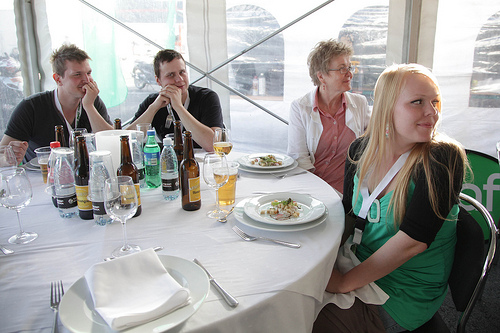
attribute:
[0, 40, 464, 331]
people — looking, sitting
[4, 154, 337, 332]
table — round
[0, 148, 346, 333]
cloth — white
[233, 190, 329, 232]
plate — white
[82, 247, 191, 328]
napkin — folded, white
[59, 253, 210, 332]
plate — white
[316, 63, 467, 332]
woman — sitting, blonde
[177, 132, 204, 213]
bottle — empty, brown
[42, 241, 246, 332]
setting — unused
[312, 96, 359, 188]
shirt — pink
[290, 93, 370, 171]
sweater — white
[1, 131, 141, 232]
glasses — empty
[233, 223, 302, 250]
fork — silver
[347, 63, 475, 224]
hair — blonde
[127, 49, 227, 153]
man — sitting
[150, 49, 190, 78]
hair — brown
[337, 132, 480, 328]
shirt — green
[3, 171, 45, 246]
glass — empty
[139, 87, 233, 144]
shirt — black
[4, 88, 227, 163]
shirts — black